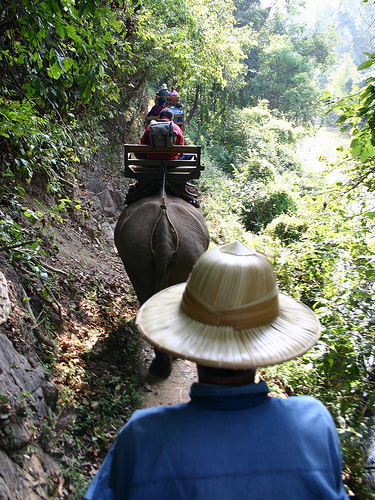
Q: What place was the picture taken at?
A: It was taken at the path.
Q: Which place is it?
A: It is a path.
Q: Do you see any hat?
A: Yes, there is a hat.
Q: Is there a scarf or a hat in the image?
A: Yes, there is a hat.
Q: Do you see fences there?
A: No, there are no fences.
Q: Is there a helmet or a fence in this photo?
A: No, there are no fences or helmets.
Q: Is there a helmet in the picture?
A: No, there are no helmets.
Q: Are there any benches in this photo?
A: Yes, there is a bench.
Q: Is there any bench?
A: Yes, there is a bench.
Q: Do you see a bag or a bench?
A: Yes, there is a bench.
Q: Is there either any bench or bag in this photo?
A: Yes, there is a bench.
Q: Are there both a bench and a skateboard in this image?
A: No, there is a bench but no skateboards.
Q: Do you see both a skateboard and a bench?
A: No, there is a bench but no skateboards.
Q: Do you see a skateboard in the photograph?
A: No, there are no skateboards.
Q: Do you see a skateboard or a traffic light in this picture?
A: No, there are no skateboards or traffic lights.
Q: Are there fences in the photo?
A: No, there are no fences.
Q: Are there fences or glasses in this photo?
A: No, there are no fences or glasses.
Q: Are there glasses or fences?
A: No, there are no fences or glasses.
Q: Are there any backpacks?
A: Yes, there is a backpack.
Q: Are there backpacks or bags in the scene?
A: Yes, there is a backpack.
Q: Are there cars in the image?
A: No, there are no cars.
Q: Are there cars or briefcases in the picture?
A: No, there are no cars or briefcases.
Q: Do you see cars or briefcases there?
A: No, there are no cars or briefcases.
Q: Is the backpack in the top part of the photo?
A: Yes, the backpack is in the top of the image.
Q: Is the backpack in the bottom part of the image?
A: No, the backpack is in the top of the image.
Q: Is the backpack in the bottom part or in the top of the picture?
A: The backpack is in the top of the image.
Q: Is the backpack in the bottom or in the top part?
A: The backpack is in the top of the image.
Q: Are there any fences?
A: No, there are no fences.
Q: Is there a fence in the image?
A: No, there are no fences.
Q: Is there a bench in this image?
A: Yes, there is a bench.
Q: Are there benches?
A: Yes, there is a bench.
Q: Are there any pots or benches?
A: Yes, there is a bench.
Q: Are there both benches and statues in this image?
A: No, there is a bench but no statues.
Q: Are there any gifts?
A: No, there are no gifts.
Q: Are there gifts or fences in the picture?
A: No, there are no gifts or fences.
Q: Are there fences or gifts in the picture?
A: No, there are no gifts or fences.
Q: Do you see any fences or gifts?
A: No, there are no gifts or fences.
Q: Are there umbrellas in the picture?
A: No, there are no umbrellas.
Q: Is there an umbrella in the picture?
A: No, there are no umbrellas.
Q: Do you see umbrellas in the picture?
A: No, there are no umbrellas.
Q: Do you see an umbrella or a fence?
A: No, there are no umbrellas or fences.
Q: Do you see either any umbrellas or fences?
A: No, there are no umbrellas or fences.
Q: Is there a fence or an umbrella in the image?
A: No, there are no umbrellas or fences.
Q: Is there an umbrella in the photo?
A: No, there are no umbrellas.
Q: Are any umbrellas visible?
A: No, there are no umbrellas.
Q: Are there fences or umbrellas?
A: No, there are no umbrellas or fences.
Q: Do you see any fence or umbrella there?
A: No, there are no umbrellas or fences.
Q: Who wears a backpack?
A: The people wear a backpack.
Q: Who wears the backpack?
A: The people wear a backpack.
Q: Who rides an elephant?
A: The people ride an elephant.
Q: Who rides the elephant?
A: The people ride an elephant.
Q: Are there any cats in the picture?
A: No, there are no cats.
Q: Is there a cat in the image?
A: No, there are no cats.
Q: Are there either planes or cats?
A: No, there are no cats or planes.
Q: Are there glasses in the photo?
A: No, there are no glasses.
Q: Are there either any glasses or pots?
A: No, there are no glasses or pots.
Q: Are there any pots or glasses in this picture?
A: No, there are no glasses or pots.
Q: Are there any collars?
A: Yes, there is a collar.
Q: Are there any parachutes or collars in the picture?
A: Yes, there is a collar.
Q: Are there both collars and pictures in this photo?
A: No, there is a collar but no pictures.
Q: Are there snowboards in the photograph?
A: No, there are no snowboards.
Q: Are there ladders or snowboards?
A: No, there are no snowboards or ladders.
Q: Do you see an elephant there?
A: Yes, there is an elephant.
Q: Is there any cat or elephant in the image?
A: Yes, there is an elephant.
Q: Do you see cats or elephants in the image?
A: Yes, there is an elephant.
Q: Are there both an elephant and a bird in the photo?
A: No, there is an elephant but no birds.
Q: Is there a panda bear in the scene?
A: No, there are no panda bears.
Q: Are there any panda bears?
A: No, there are no panda bears.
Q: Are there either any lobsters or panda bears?
A: No, there are no panda bears or lobsters.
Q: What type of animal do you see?
A: The animal is an elephant.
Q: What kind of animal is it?
A: The animal is an elephant.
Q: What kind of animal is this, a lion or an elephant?
A: This is an elephant.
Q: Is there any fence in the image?
A: No, there are no fences.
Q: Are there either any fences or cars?
A: No, there are no fences or cars.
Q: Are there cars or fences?
A: No, there are no fences or cars.